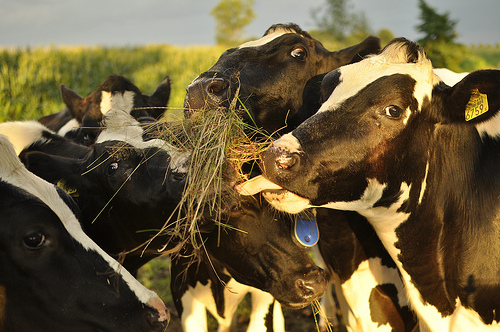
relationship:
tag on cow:
[440, 57, 495, 128] [235, 37, 498, 332]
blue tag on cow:
[276, 223, 340, 248] [183, 43, 492, 219]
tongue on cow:
[235, 166, 276, 198] [235, 37, 498, 332]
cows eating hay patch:
[0, 21, 340, 273] [165, 111, 256, 191]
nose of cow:
[249, 132, 302, 190] [235, 37, 498, 332]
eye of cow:
[384, 102, 403, 119] [234, 37, 498, 329]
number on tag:
[465, 101, 487, 117] [460, 85, 495, 123]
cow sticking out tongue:
[234, 37, 498, 329] [233, 172, 282, 195]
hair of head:
[390, 31, 425, 65] [239, 35, 449, 228]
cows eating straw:
[2, 18, 498, 330] [76, 105, 290, 294]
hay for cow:
[73, 73, 290, 293] [163, 169, 326, 330]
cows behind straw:
[38, 75, 171, 148] [200, 152, 231, 182]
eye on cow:
[15, 219, 55, 251] [235, 37, 498, 332]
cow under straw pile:
[197, 165, 335, 325] [112, 62, 298, 287]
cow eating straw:
[235, 37, 498, 332] [179, 103, 259, 204]